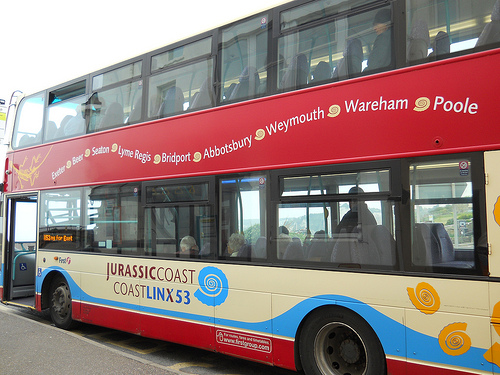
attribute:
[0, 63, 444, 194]
bus — red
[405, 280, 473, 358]
swirls — orange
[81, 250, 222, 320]
text — red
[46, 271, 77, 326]
tire — black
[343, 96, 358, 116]
letter — white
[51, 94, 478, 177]
text — white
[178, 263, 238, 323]
symbol — swirl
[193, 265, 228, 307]
swirl — blue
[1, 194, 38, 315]
door — open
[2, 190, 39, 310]
door — open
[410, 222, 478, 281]
seats — gray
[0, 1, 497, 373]
bus — double, red, white, blue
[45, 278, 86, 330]
tire — black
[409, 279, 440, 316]
swirls — orange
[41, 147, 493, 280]
window — clear